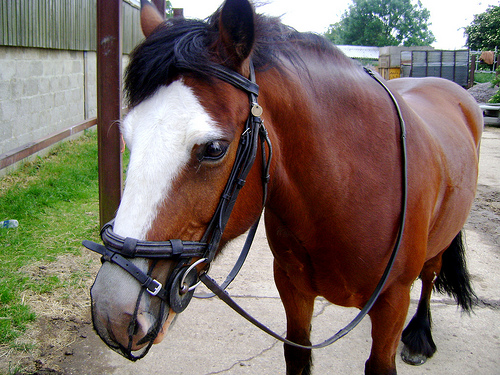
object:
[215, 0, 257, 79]
ear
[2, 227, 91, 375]
ground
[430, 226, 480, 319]
tail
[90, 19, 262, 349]
face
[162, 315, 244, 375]
ground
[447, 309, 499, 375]
ground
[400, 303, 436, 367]
hoof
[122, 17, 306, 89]
mane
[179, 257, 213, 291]
bridle ring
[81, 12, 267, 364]
bridle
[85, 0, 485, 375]
horse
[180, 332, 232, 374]
staples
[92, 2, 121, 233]
red pole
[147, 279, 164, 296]
buckle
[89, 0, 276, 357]
head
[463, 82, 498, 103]
dirt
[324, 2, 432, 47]
tree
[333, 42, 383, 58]
building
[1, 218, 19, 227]
bottle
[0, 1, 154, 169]
wall